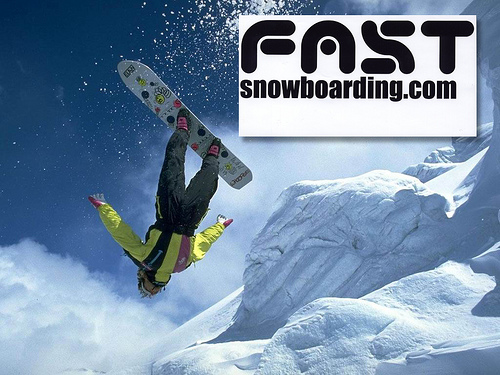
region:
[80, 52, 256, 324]
snowboarder doing a flip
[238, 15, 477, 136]
advertisement for Fast snowboarding.com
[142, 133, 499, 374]
snow covered mountain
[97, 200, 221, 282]
yellow black and pink coat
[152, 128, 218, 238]
black snowboarding pants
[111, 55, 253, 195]
white snowboard in the air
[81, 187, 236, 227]
pink and white gloves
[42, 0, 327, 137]
snow flying of the snowboard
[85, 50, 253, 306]
the snowboarder is inverted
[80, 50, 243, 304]
his back is arched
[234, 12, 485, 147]
black logo for snowboarding company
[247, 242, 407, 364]
mountains covered in white snow and ice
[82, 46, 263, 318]
snowboarder upside down in the air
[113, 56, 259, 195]
white snowboard with stickers and logos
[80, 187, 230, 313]
yellow jacket with black and pink stripes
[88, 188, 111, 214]
pink and white gloves on hand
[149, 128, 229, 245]
black snowboarding pants with yellow details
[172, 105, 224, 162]
pink and black snowboarding boots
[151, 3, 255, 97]
snow coming off the snowboard in the air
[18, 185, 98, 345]
clouds in the sky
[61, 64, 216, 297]
man doing snowboarding trick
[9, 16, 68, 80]
white clouds in blue sky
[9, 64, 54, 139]
white clouds in blue sky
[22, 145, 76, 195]
white clouds in blue sky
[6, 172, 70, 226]
white clouds in blue sky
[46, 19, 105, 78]
white clouds in blue sky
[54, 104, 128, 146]
white clouds in blue sky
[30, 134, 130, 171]
white clouds in blue sky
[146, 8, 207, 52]
white clouds in blue sky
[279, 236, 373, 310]
snow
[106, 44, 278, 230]
a snowboard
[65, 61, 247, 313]
a person snowboarding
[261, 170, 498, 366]
snow on the mountain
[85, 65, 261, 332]
a person wearing black boots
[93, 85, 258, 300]
a person wearing pink straps on boots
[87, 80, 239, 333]
a person wearing black snow pants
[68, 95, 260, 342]
a person wearing a yellow jacket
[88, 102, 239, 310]
a person wearing snow goggles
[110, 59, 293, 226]
a white snowboard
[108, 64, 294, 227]
a snowboard with stickers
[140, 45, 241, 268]
man snow boarding off cliff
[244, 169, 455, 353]
thick white snow on mountain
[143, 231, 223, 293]
yellow jacket on boarder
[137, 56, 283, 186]
white snow board on man's feet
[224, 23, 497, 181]
white fast logo in corner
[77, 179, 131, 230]
red gloves on boarder's hands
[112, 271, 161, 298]
goggles over boarder's eyes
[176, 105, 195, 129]
black shoes with pink laces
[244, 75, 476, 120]
website on sing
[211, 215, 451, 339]
cracks in ice on mountain